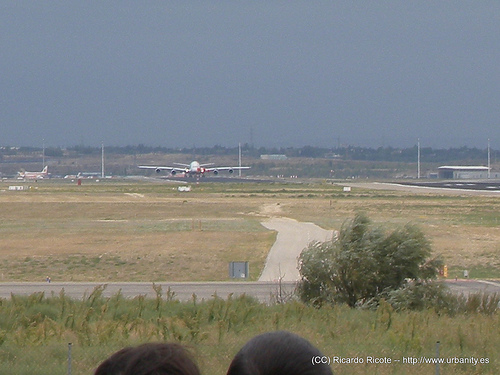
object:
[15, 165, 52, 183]
aircraft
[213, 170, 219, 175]
engine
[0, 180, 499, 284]
dry grass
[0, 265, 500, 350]
bushy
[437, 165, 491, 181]
hangar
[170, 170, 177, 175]
engine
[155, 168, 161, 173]
engine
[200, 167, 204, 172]
lights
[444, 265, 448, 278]
pole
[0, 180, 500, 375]
grass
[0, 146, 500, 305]
airport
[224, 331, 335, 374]
person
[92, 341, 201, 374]
person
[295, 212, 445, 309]
tree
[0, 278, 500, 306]
runway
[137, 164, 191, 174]
wing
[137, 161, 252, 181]
aircraft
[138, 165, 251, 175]
wings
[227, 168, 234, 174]
engine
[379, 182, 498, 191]
runway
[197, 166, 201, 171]
tail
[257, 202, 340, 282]
runway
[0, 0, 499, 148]
sky